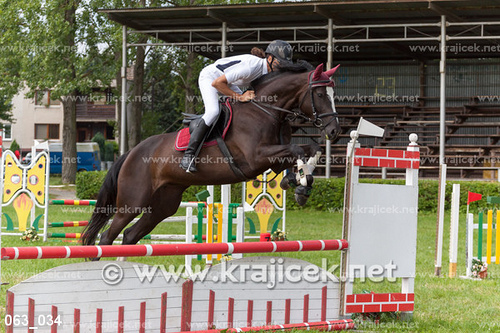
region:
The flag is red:
[459, 177, 491, 212]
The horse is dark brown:
[95, 121, 272, 221]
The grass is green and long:
[427, 277, 487, 322]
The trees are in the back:
[50, 75, 185, 165]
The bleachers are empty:
[372, 66, 492, 206]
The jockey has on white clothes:
[170, 58, 300, 143]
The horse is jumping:
[73, 156, 324, 303]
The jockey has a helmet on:
[250, 30, 318, 75]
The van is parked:
[30, 121, 115, 181]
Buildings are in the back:
[9, 47, 187, 224]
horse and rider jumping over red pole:
[10, 27, 348, 327]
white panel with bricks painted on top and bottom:
[341, 135, 416, 315]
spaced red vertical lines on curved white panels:
[2, 251, 339, 323]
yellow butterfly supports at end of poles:
[5, 137, 285, 234]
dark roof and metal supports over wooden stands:
[110, 5, 490, 172]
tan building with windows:
[0, 70, 61, 147]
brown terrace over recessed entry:
[70, 77, 116, 142]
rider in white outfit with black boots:
[180, 35, 296, 170]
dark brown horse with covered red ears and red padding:
[75, 60, 340, 240]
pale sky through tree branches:
[0, 0, 180, 185]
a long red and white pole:
[0, 231, 345, 256]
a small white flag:
[352, 113, 384, 142]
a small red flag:
[467, 185, 487, 207]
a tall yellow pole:
[485, 206, 494, 265]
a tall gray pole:
[433, 13, 452, 173]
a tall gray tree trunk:
[56, 3, 87, 182]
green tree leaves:
[1, 0, 126, 112]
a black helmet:
[263, 35, 293, 62]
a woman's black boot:
[180, 117, 208, 177]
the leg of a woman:
[197, 65, 219, 125]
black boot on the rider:
[179, 115, 210, 174]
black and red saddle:
[171, 95, 233, 152]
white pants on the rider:
[196, 64, 226, 126]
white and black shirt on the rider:
[212, 54, 270, 87]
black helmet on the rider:
[263, 38, 296, 68]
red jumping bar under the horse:
[1, 234, 350, 265]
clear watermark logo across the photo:
[97, 258, 402, 285]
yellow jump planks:
[484, 205, 499, 269]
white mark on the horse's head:
[322, 83, 343, 123]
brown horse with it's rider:
[77, 53, 344, 261]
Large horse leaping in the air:
[91, 26, 345, 286]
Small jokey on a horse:
[147, 21, 364, 213]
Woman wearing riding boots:
[165, 21, 297, 193]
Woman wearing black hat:
[182, 34, 300, 174]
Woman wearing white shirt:
[160, 21, 297, 178]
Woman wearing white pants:
[161, 16, 320, 186]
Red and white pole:
[0, 236, 352, 261]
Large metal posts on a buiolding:
[114, 24, 496, 49]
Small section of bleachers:
[445, 99, 496, 167]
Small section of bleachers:
[383, 90, 467, 196]